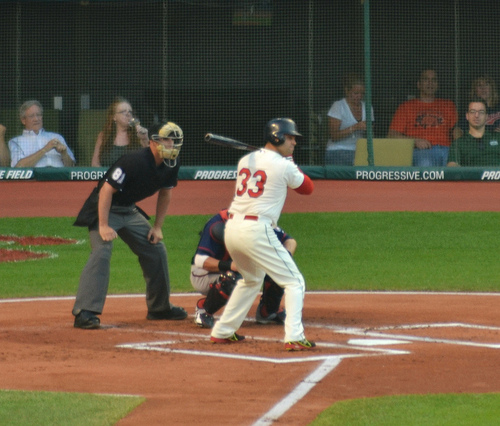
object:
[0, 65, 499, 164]
fans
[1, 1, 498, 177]
fence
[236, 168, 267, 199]
33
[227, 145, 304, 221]
shirt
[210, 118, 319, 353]
batter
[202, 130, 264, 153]
bat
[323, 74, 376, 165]
woman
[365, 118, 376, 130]
cellphone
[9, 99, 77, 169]
man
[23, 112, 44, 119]
glasses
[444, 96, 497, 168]
man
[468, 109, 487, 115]
glasses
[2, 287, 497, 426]
stripes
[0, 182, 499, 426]
field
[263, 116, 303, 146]
helmet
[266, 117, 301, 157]
head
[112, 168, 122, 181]
8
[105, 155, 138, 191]
sleeve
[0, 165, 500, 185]
progressive banner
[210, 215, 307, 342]
pants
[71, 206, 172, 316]
pants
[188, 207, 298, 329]
catcher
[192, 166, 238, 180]
progressive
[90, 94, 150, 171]
woman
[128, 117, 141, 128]
wine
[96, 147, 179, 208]
shirt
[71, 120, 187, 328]
umpire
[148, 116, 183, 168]
helmet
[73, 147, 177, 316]
clothing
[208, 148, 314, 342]
uniform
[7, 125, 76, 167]
shirt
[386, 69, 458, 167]
man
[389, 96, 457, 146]
t-shirt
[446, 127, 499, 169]
shirt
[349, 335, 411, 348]
home plate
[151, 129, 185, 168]
face guard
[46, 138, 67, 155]
hands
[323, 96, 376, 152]
shirt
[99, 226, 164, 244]
hands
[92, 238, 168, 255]
knees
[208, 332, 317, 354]
cleats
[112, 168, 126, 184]
81